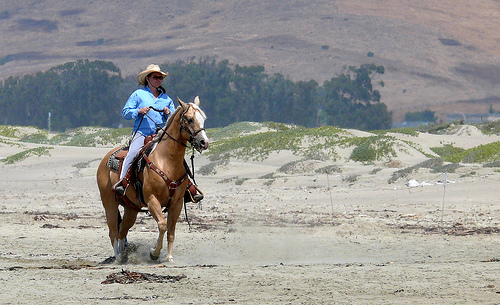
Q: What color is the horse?
A: Brown and white.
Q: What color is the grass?
A: Green.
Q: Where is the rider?
A: On the horse.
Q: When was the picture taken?
A: Daytime.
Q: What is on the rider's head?
A: A hat.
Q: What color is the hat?
A: Tan.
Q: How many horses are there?
A: One.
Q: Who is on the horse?
A: The rider.